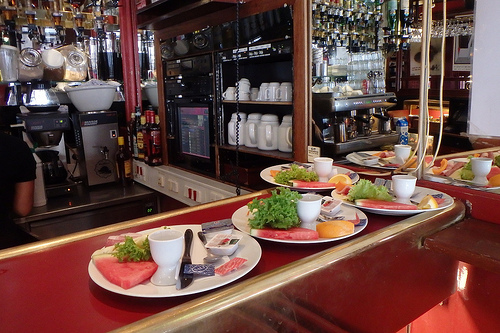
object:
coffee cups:
[222, 77, 258, 101]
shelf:
[222, 100, 293, 105]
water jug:
[277, 115, 293, 153]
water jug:
[257, 113, 280, 150]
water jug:
[245, 113, 262, 148]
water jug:
[227, 112, 247, 146]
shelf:
[218, 144, 295, 161]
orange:
[316, 220, 355, 239]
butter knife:
[175, 228, 194, 290]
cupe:
[148, 229, 186, 286]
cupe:
[296, 193, 322, 231]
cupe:
[390, 175, 418, 204]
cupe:
[311, 156, 334, 183]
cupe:
[389, 144, 412, 165]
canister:
[15, 46, 44, 82]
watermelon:
[250, 226, 320, 240]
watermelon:
[355, 199, 418, 210]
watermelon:
[287, 179, 336, 188]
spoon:
[197, 231, 220, 263]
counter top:
[0, 186, 465, 333]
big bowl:
[64, 78, 118, 111]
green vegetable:
[247, 187, 304, 230]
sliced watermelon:
[91, 253, 158, 290]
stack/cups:
[234, 78, 250, 101]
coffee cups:
[256, 82, 292, 102]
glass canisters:
[0, 44, 89, 82]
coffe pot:
[21, 78, 79, 201]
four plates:
[87, 157, 454, 298]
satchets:
[182, 252, 246, 275]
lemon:
[328, 173, 352, 184]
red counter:
[11, 260, 85, 330]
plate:
[86, 224, 262, 298]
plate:
[231, 194, 370, 244]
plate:
[331, 175, 455, 217]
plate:
[259, 157, 360, 193]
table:
[0, 142, 500, 331]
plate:
[346, 150, 435, 171]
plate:
[422, 157, 499, 194]